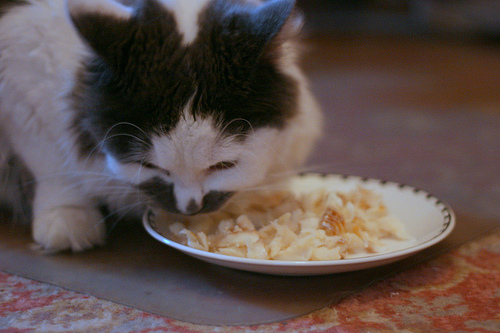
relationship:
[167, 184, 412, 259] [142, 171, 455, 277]
cat food on plate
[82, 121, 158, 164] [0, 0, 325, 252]
whisker on cat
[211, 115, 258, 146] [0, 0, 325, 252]
whisker on cat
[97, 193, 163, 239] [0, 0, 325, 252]
whisker on cat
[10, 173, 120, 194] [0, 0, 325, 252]
whisker on cat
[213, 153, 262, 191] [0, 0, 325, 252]
whisker on cat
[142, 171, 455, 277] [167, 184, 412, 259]
plate has cat food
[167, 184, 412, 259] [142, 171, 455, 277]
cat food in plate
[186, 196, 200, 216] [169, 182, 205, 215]
dot on cat's nose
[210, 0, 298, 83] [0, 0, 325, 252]
ear on cat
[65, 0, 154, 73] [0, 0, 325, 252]
ear on cat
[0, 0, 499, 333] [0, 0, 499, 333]
carpet protecting carpet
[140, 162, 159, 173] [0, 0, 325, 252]
eye on cat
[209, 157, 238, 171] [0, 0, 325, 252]
eye on cat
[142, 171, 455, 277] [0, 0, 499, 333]
plate on carpet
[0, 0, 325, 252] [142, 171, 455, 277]
cat eating from plate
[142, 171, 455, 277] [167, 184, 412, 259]
plate with cat food